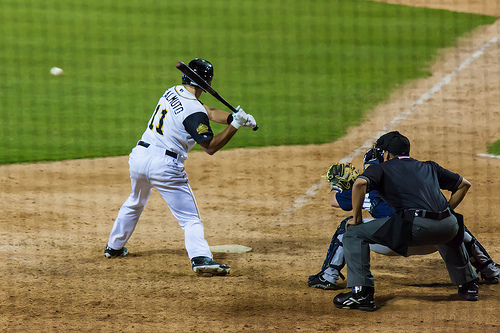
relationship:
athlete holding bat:
[101, 56, 258, 277] [170, 57, 260, 131]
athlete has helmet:
[101, 56, 258, 277] [175, 47, 222, 94]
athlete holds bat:
[101, 56, 258, 277] [173, 54, 276, 137]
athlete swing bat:
[105, 56, 259, 273] [170, 57, 260, 131]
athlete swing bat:
[101, 56, 258, 277] [170, 57, 260, 131]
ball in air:
[50, 66, 64, 76] [34, 48, 80, 92]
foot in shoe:
[103, 242, 126, 252] [89, 234, 137, 268]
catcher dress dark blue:
[330, 128, 482, 313] [343, 155, 467, 287]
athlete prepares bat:
[101, 56, 258, 277] [156, 54, 251, 120]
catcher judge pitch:
[330, 128, 482, 313] [34, 23, 269, 287]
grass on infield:
[0, 6, 498, 171] [10, 8, 497, 141]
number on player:
[147, 103, 167, 135] [101, 59, 257, 274]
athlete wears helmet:
[101, 56, 258, 277] [180, 57, 215, 84]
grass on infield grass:
[15, 10, 424, 111] [15, 9, 448, 122]